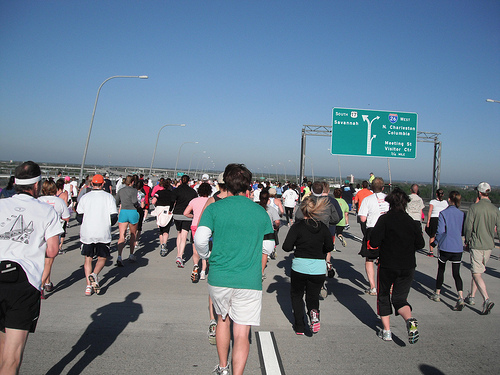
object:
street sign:
[373, 131, 397, 149]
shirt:
[194, 195, 273, 291]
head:
[221, 162, 254, 197]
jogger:
[74, 172, 117, 297]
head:
[89, 172, 106, 189]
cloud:
[8, 110, 495, 201]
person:
[72, 174, 120, 296]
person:
[0, 157, 68, 373]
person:
[115, 174, 147, 264]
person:
[357, 173, 387, 293]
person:
[188, 161, 278, 373]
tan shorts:
[202, 281, 265, 331]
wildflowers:
[75, 154, 281, 291]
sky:
[4, 0, 499, 213]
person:
[367, 189, 424, 343]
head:
[382, 187, 412, 211]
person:
[52, 173, 70, 204]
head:
[54, 177, 67, 189]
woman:
[424, 187, 469, 314]